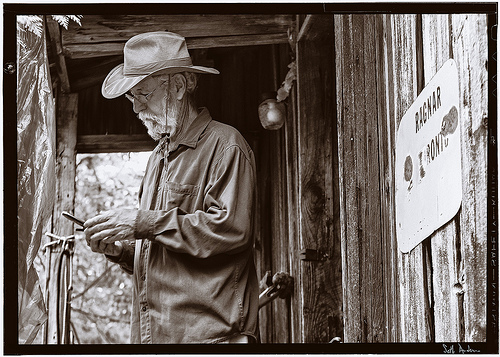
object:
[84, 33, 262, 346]
man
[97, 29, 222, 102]
hat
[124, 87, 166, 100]
glasses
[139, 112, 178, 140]
beard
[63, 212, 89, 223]
cellphone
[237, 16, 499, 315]
building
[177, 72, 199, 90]
hair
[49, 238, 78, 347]
rope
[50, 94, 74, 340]
beam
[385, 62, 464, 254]
sign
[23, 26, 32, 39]
leaves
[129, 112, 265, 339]
shirt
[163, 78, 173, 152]
string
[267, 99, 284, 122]
lamp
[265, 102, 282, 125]
bulb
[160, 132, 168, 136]
knob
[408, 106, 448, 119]
writing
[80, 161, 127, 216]
tree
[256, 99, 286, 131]
lighting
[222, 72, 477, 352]
house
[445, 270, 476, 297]
fern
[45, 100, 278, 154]
rooftop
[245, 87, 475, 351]
cabin